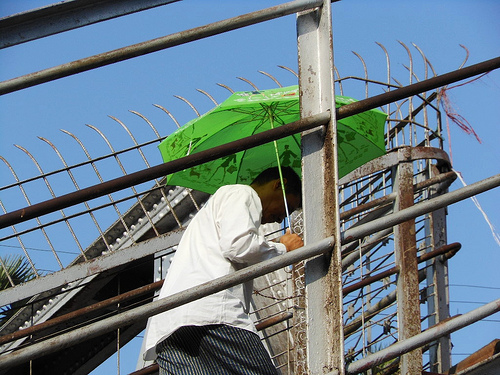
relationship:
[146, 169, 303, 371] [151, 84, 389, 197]
man holding umbrella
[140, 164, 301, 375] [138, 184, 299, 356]
man wearing shirt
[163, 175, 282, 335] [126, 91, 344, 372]
shirt on man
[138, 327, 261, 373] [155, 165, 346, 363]
pants of man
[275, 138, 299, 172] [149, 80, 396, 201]
characters are on umbrella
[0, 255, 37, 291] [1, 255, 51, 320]
leaves of palm trees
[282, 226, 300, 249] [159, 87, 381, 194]
hand holding umbrella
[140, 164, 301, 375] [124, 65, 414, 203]
man holding umbrella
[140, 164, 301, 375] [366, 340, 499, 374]
man on stairs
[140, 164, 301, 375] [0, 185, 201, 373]
man on stairs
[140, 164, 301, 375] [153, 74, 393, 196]
man holding umbrella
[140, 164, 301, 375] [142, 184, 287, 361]
man wearing white coat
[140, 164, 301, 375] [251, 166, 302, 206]
man has black hair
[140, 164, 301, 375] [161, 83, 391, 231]
man holding umbrella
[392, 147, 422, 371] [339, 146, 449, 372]
metal post holding poles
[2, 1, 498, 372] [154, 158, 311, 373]
railing near man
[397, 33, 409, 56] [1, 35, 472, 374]
spike on top of fence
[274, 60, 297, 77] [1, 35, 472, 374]
spike on top of fence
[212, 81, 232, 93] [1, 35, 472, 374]
spike on top of fence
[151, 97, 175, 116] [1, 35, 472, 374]
spike on top of fence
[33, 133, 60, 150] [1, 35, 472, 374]
spike on top of fence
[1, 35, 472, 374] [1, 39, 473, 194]
fence has top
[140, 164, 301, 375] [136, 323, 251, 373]
man wearing bottoms